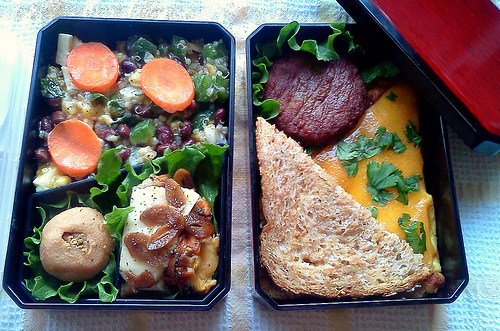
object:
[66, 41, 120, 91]
carrot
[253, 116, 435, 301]
bread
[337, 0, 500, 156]
top of container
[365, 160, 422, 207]
parsley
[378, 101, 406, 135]
cheese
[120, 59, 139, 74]
bean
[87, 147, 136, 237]
leaf of lettuce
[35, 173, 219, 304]
food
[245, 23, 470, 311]
container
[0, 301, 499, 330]
tablecloth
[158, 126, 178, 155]
kidney beans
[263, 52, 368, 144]
meat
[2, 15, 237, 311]
bento box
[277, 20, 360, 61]
leaf of lettuce